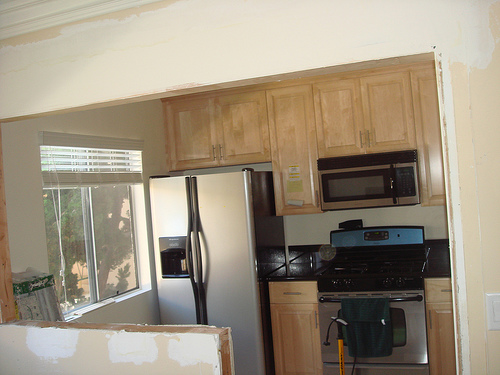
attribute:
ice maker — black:
[154, 232, 196, 280]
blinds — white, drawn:
[29, 125, 149, 189]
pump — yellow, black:
[322, 307, 349, 373]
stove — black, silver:
[316, 224, 431, 372]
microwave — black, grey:
[308, 152, 425, 212]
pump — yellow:
[323, 309, 360, 374]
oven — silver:
[299, 207, 432, 367]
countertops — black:
[268, 243, 333, 283]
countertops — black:
[425, 239, 450, 278]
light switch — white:
[475, 274, 498, 338]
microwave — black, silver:
[311, 153, 442, 225]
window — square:
[41, 185, 136, 297]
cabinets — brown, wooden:
[162, 93, 219, 172]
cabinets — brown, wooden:
[215, 88, 273, 169]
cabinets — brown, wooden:
[266, 83, 321, 215]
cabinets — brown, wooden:
[308, 77, 367, 159]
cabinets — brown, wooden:
[361, 67, 415, 153]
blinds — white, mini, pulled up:
[44, 145, 150, 180]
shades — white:
[32, 132, 149, 182]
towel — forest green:
[336, 294, 397, 360]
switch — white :
[480, 287, 497, 334]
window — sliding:
[36, 131, 152, 319]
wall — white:
[0, 103, 183, 323]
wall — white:
[0, 0, 498, 373]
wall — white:
[179, 163, 449, 273]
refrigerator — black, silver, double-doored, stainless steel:
[141, 166, 281, 373]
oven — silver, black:
[319, 292, 426, 367]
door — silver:
[145, 174, 197, 323]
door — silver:
[190, 169, 267, 373]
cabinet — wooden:
[160, 88, 219, 174]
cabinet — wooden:
[214, 79, 273, 169]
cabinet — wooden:
[260, 75, 324, 216]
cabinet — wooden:
[310, 70, 367, 160]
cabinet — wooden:
[355, 65, 416, 154]